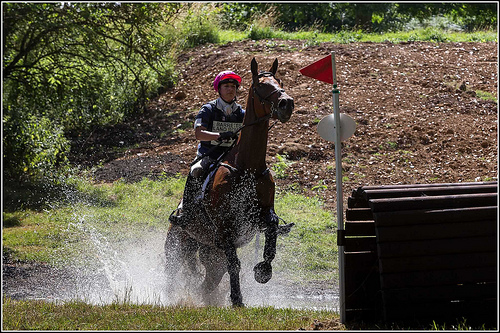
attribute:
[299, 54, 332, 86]
flag — red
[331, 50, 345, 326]
pole — metal, silver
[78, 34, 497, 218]
dirt — brown, hilly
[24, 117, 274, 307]
water — spraying, sprayed, splashing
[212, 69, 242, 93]
helmet — pink, red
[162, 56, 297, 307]
horse — brown, large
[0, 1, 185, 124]
tree — green, leafy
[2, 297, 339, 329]
grass — green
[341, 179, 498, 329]
structure — wooden, circular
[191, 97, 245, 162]
uniform — blue, white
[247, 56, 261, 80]
ear — sticking up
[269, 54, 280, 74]
ear — sticking up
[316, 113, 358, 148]
sign — round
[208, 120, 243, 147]
sign — white